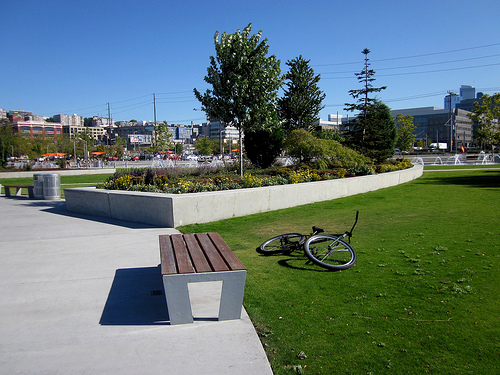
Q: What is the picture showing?
A: It is showing a park.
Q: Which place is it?
A: It is a park.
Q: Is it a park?
A: Yes, it is a park.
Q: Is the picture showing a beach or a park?
A: It is showing a park.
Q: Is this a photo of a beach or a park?
A: It is showing a park.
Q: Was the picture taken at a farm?
A: No, the picture was taken in a park.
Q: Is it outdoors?
A: Yes, it is outdoors.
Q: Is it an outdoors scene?
A: Yes, it is outdoors.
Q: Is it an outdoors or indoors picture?
A: It is outdoors.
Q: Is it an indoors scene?
A: No, it is outdoors.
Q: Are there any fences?
A: No, there are no fences.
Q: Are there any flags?
A: No, there are no flags.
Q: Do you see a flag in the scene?
A: No, there are no flags.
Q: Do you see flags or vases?
A: No, there are no flags or vases.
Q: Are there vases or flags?
A: No, there are no flags or vases.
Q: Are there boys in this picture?
A: No, there are no boys.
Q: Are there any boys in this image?
A: No, there are no boys.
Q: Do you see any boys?
A: No, there are no boys.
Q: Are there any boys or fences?
A: No, there are no boys or fences.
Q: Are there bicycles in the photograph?
A: Yes, there is a bicycle.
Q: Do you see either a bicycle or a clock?
A: Yes, there is a bicycle.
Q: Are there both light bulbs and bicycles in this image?
A: No, there is a bicycle but no light bulbs.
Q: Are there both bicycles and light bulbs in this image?
A: No, there is a bicycle but no light bulbs.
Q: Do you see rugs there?
A: No, there are no rugs.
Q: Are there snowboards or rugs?
A: No, there are no rugs or snowboards.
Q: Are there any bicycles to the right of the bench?
A: Yes, there is a bicycle to the right of the bench.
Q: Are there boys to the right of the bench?
A: No, there is a bicycle to the right of the bench.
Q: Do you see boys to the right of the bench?
A: No, there is a bicycle to the right of the bench.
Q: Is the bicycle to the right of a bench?
A: Yes, the bicycle is to the right of a bench.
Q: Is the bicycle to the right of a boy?
A: No, the bicycle is to the right of a bench.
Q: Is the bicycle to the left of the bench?
A: No, the bicycle is to the right of the bench.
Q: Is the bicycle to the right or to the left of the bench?
A: The bicycle is to the right of the bench.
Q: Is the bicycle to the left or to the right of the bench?
A: The bicycle is to the right of the bench.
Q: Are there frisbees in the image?
A: No, there are no frisbees.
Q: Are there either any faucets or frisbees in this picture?
A: No, there are no frisbees or faucets.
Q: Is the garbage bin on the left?
A: Yes, the garbage bin is on the left of the image.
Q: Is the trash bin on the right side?
A: No, the trash bin is on the left of the image.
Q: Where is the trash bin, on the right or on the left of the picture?
A: The trash bin is on the left of the image.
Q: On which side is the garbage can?
A: The garbage can is on the left of the image.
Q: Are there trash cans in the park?
A: Yes, there is a trash can in the park.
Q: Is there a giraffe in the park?
A: No, there is a trash can in the park.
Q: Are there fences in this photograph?
A: No, there are no fences.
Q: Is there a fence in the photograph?
A: No, there are no fences.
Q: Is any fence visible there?
A: No, there are no fences.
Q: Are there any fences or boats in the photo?
A: No, there are no fences or boats.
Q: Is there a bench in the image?
A: Yes, there is a bench.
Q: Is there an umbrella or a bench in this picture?
A: Yes, there is a bench.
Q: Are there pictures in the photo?
A: No, there are no pictures.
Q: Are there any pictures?
A: No, there are no pictures.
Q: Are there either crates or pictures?
A: No, there are no pictures or crates.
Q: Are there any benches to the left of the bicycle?
A: Yes, there is a bench to the left of the bicycle.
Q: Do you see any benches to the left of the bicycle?
A: Yes, there is a bench to the left of the bicycle.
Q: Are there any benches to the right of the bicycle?
A: No, the bench is to the left of the bicycle.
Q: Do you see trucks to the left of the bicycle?
A: No, there is a bench to the left of the bicycle.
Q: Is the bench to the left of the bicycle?
A: Yes, the bench is to the left of the bicycle.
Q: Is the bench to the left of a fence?
A: No, the bench is to the left of the bicycle.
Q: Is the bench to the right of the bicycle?
A: No, the bench is to the left of the bicycle.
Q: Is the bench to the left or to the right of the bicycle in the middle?
A: The bench is to the left of the bicycle.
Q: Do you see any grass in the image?
A: Yes, there is grass.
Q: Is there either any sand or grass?
A: Yes, there is grass.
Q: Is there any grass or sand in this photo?
A: Yes, there is grass.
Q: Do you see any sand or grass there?
A: Yes, there is grass.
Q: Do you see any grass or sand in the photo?
A: Yes, there is grass.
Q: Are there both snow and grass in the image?
A: No, there is grass but no snow.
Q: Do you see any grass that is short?
A: Yes, there is short grass.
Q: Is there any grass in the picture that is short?
A: Yes, there is grass that is short.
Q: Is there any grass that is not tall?
A: Yes, there is short grass.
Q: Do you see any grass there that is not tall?
A: Yes, there is short grass.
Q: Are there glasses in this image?
A: No, there are no glasses.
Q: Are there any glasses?
A: No, there are no glasses.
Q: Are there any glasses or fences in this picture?
A: No, there are no glasses or fences.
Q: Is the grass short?
A: Yes, the grass is short.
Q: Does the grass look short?
A: Yes, the grass is short.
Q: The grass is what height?
A: The grass is short.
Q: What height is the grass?
A: The grass is short.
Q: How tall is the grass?
A: The grass is short.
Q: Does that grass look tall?
A: No, the grass is short.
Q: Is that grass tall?
A: No, the grass is short.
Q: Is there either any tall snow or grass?
A: No, there is grass but it is short.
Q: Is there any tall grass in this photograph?
A: No, there is grass but it is short.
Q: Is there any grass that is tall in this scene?
A: No, there is grass but it is short.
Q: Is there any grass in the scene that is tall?
A: No, there is grass but it is short.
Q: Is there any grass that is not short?
A: No, there is grass but it is short.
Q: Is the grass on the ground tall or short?
A: The grass is short.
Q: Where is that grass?
A: The grass is on the ground.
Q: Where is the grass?
A: The grass is on the ground.